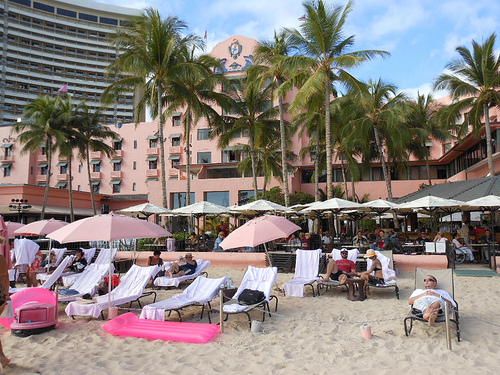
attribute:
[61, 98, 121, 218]
tree — tall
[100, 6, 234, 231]
tree — tall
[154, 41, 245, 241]
tree — tall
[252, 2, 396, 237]
tree — tall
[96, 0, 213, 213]
tree — tall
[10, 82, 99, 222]
tree — tall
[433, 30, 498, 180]
tree — tall, green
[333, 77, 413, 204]
tree — green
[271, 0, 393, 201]
tree — tall, green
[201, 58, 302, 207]
tree — green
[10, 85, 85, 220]
tree — tall, green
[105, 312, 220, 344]
inflatable object — pink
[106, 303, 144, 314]
chain — forming a barrier, small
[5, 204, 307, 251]
umbrellas — pink, in a row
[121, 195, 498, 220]
umbrellas — white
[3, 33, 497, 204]
building — pink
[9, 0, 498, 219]
palm trees — tall, green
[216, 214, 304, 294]
umbrella — large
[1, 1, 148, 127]
building — tall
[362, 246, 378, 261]
hat — yellow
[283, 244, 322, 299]
beach towel — large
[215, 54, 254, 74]
decoration — blue